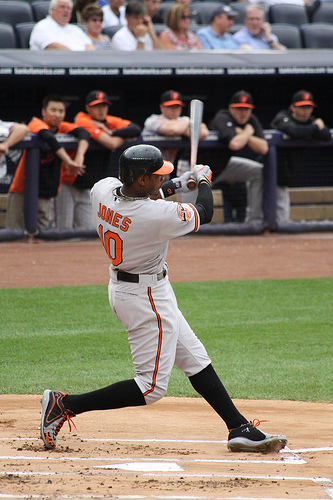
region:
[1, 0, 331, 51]
spectators sitting in the bleachers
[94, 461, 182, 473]
a white home plate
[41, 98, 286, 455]
a baseball player swinging his bat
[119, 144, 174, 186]
man wearing a black hard hat with an orange visor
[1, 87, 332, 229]
men standing in the dugout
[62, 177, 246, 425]
man wearing a white, black and orange uniform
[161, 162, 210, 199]
man wearing gloves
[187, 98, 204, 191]
a baseball bat in man's hands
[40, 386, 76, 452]
a white, black and orange shoe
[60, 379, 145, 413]
long black socks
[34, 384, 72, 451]
a cleat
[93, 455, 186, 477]
home plate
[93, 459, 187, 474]
home plate is white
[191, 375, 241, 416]
black socks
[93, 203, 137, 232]
writing on the jersey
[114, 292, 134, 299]
pocket on the pants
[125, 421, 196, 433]
the dirt is brown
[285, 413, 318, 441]
turf on the baseball field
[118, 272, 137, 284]
black belt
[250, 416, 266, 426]
orange shoe laces on the cleat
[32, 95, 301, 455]
A baseball player after swinging the bat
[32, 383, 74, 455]
A gray, black and orange baseball cleat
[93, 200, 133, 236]
Last name "Jones"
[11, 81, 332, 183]
Teammates watching from the dugout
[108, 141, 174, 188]
A black baseball helmet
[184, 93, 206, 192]
A baseball bat in action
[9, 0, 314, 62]
Baseball fans watching from the stands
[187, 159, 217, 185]
A batter's glove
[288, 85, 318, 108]
A baseball team hat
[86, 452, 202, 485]
Home plate on a baseball field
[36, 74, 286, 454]
baseball player swinging a bat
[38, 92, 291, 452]
baseball player in grey and orange uniform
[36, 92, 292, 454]
baseball player with black socks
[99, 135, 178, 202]
baseball player with black helmet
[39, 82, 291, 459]
baseball player in batter's box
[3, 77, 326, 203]
men waiting in the dugout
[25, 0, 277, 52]
spectators in the stands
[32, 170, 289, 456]
grey baseball uniform with orange letters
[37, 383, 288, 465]
man wearing grey, black, and orange shoes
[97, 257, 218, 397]
grey pants with orange stripe